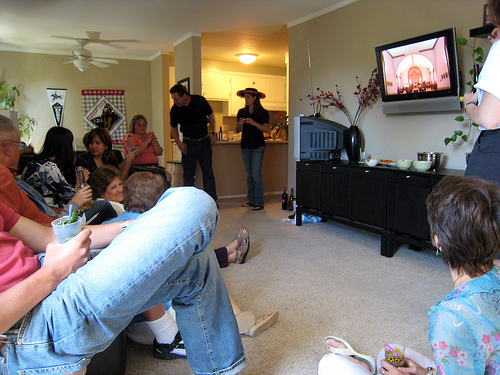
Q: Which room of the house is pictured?
A: It is a living room.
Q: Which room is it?
A: It is a living room.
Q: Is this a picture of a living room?
A: Yes, it is showing a living room.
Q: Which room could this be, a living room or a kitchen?
A: It is a living room.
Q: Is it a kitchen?
A: No, it is a living room.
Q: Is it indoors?
A: Yes, it is indoors.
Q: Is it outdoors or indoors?
A: It is indoors.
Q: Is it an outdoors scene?
A: No, it is indoors.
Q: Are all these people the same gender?
A: No, they are both male and female.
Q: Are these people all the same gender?
A: No, they are both male and female.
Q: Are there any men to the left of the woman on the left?
A: Yes, there is a man to the left of the woman.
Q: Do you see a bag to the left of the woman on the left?
A: No, there is a man to the left of the woman.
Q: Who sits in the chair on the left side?
A: The man sits in the chair.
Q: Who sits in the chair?
A: The man sits in the chair.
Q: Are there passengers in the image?
A: No, there are no passengers.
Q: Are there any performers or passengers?
A: No, there are no passengers or performers.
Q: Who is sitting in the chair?
A: The man is sitting in the chair.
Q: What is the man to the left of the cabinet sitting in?
A: The man is sitting in the chair.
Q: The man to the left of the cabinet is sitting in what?
A: The man is sitting in the chair.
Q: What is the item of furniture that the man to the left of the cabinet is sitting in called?
A: The piece of furniture is a chair.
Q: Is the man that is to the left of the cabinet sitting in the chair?
A: Yes, the man is sitting in the chair.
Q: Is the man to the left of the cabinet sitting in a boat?
A: No, the man is sitting in the chair.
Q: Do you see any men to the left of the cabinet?
A: Yes, there is a man to the left of the cabinet.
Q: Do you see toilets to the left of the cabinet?
A: No, there is a man to the left of the cabinet.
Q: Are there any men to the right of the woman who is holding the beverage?
A: No, the man is to the left of the woman.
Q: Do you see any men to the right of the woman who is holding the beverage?
A: No, the man is to the left of the woman.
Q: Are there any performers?
A: No, there are no performers.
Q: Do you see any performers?
A: No, there are no performers.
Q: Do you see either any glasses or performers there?
A: No, there are no performers or glasses.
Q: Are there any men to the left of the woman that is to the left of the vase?
A: Yes, there is a man to the left of the woman.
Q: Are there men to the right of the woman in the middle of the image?
A: No, the man is to the left of the woman.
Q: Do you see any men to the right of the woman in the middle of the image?
A: No, the man is to the left of the woman.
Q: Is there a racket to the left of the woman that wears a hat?
A: No, there is a man to the left of the woman.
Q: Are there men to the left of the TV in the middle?
A: Yes, there is a man to the left of the television.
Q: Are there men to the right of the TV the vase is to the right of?
A: No, the man is to the left of the television.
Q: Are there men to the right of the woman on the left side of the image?
A: Yes, there is a man to the right of the woman.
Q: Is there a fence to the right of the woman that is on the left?
A: No, there is a man to the right of the woman.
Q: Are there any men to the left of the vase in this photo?
A: Yes, there is a man to the left of the vase.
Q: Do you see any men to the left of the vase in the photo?
A: Yes, there is a man to the left of the vase.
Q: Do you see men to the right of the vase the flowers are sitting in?
A: No, the man is to the left of the vase.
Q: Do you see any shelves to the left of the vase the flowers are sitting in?
A: No, there is a man to the left of the vase.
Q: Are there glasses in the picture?
A: No, there are no glasses.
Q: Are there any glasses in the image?
A: No, there are no glasses.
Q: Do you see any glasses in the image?
A: No, there are no glasses.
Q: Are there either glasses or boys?
A: No, there are no glasses or boys.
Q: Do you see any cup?
A: Yes, there is a cup.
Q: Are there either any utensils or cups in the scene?
A: Yes, there is a cup.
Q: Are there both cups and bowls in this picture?
A: Yes, there are both a cup and a bowl.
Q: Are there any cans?
A: No, there are no cans.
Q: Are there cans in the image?
A: No, there are no cans.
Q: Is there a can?
A: No, there are no cans.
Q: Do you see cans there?
A: No, there are no cans.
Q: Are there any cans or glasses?
A: No, there are no cans or glasses.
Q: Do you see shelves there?
A: No, there are no shelves.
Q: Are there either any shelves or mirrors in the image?
A: No, there are no shelves or mirrors.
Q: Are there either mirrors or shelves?
A: No, there are no shelves or mirrors.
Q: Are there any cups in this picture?
A: Yes, there is a cup.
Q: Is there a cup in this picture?
A: Yes, there is a cup.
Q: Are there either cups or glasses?
A: Yes, there is a cup.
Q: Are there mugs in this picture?
A: No, there are no mugs.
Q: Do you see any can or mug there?
A: No, there are no mugs or cans.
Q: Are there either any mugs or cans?
A: No, there are no mugs or cans.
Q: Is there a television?
A: Yes, there is a television.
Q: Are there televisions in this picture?
A: Yes, there is a television.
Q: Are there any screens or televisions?
A: Yes, there is a television.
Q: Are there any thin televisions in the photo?
A: Yes, there is a thin television.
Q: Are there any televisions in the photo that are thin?
A: Yes, there is a thin television.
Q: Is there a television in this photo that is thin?
A: Yes, there is a television that is thin.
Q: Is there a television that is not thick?
A: Yes, there is a thin television.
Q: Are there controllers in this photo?
A: No, there are no controllers.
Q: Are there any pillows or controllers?
A: No, there are no controllers or pillows.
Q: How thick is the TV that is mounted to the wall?
A: The TV is thin.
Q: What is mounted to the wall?
A: The TV is mounted to the wall.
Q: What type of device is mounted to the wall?
A: The device is a television.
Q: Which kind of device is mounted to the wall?
A: The device is a television.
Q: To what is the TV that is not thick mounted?
A: The television is mounted to the wall.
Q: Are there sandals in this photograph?
A: Yes, there are sandals.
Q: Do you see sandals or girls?
A: Yes, there are sandals.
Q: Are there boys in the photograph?
A: No, there are no boys.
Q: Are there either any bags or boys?
A: No, there are no boys or bags.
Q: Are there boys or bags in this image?
A: No, there are no boys or bags.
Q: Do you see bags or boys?
A: No, there are no boys or bags.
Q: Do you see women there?
A: Yes, there is a woman.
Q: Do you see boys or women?
A: Yes, there is a woman.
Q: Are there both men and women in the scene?
A: Yes, there are both a woman and a man.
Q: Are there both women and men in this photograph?
A: Yes, there are both a woman and a man.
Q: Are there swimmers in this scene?
A: No, there are no swimmers.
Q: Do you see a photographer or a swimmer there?
A: No, there are no swimmers or photographers.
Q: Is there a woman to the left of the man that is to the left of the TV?
A: Yes, there is a woman to the left of the man.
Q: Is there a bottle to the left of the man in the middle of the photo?
A: No, there is a woman to the left of the man.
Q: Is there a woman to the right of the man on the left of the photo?
A: Yes, there is a woman to the right of the man.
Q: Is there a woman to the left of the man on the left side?
A: No, the woman is to the right of the man.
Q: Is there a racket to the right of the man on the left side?
A: No, there is a woman to the right of the man.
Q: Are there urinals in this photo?
A: No, there are no urinals.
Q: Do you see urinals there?
A: No, there are no urinals.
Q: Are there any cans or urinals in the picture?
A: No, there are no urinals or cans.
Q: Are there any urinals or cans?
A: No, there are no urinals or cans.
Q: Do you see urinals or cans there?
A: No, there are no urinals or cans.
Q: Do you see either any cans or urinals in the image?
A: No, there are no urinals or cans.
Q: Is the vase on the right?
A: Yes, the vase is on the right of the image.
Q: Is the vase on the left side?
A: No, the vase is on the right of the image.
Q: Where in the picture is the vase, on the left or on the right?
A: The vase is on the right of the image.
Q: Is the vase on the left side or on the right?
A: The vase is on the right of the image.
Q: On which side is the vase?
A: The vase is on the right of the image.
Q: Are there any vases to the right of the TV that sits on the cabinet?
A: Yes, there is a vase to the right of the television.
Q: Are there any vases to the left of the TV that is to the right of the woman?
A: No, the vase is to the right of the television.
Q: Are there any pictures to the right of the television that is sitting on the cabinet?
A: No, there is a vase to the right of the television.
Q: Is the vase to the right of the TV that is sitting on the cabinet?
A: Yes, the vase is to the right of the TV.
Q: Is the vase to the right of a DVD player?
A: No, the vase is to the right of the TV.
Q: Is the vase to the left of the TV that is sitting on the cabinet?
A: No, the vase is to the right of the TV.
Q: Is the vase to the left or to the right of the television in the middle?
A: The vase is to the right of the television.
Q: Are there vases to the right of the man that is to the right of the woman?
A: Yes, there is a vase to the right of the man.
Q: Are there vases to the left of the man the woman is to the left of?
A: No, the vase is to the right of the man.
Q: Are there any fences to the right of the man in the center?
A: No, there is a vase to the right of the man.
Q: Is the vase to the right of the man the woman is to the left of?
A: Yes, the vase is to the right of the man.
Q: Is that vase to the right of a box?
A: No, the vase is to the right of the man.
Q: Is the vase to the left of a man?
A: No, the vase is to the right of a man.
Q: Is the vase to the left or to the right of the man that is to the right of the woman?
A: The vase is to the right of the man.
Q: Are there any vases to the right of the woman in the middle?
A: Yes, there is a vase to the right of the woman.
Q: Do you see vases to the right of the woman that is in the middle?
A: Yes, there is a vase to the right of the woman.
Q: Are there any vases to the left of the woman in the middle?
A: No, the vase is to the right of the woman.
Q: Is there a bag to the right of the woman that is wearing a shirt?
A: No, there is a vase to the right of the woman.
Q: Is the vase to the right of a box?
A: No, the vase is to the right of the woman.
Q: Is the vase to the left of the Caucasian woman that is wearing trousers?
A: No, the vase is to the right of the woman.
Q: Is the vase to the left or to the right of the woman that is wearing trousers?
A: The vase is to the right of the woman.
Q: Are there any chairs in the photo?
A: Yes, there is a chair.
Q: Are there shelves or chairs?
A: Yes, there is a chair.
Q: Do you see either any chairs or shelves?
A: Yes, there is a chair.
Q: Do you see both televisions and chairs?
A: Yes, there are both a chair and a television.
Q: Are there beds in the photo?
A: No, there are no beds.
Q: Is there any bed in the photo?
A: No, there are no beds.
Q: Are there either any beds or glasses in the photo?
A: No, there are no beds or glasses.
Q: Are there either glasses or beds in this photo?
A: No, there are no beds or glasses.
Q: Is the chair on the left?
A: Yes, the chair is on the left of the image.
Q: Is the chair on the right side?
A: No, the chair is on the left of the image.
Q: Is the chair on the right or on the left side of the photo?
A: The chair is on the left of the image.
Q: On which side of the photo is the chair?
A: The chair is on the left of the image.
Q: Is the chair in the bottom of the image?
A: Yes, the chair is in the bottom of the image.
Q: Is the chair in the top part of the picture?
A: No, the chair is in the bottom of the image.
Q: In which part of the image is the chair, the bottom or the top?
A: The chair is in the bottom of the image.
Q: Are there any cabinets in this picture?
A: Yes, there is a cabinet.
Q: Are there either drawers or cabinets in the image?
A: Yes, there is a cabinet.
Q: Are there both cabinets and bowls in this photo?
A: Yes, there are both a cabinet and a bowl.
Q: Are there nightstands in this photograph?
A: No, there are no nightstands.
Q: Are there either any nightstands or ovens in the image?
A: No, there are no nightstands or ovens.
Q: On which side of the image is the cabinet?
A: The cabinet is on the right of the image.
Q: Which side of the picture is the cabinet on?
A: The cabinet is on the right of the image.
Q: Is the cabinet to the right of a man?
A: Yes, the cabinet is to the right of a man.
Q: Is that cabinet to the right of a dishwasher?
A: No, the cabinet is to the right of a man.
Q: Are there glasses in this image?
A: No, there are no glasses.